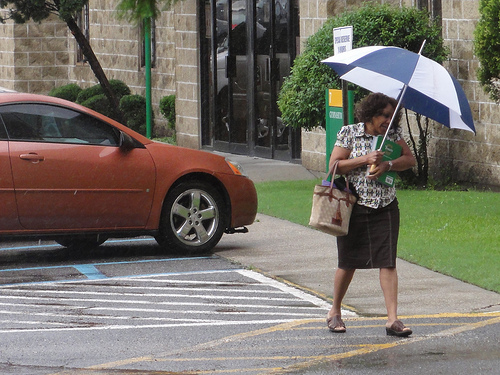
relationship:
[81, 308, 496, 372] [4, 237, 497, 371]
lines in lot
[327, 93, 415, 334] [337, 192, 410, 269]
woman has skirt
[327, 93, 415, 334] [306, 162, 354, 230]
woman carrying a tote bag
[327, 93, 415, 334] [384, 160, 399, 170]
woman wearing a watch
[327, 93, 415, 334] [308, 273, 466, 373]
woman walking on sidewalk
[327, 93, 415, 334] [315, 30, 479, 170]
woman carrying umbrella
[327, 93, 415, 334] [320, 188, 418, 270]
woman wearing a skirt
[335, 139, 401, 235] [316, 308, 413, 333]
blouse and sandals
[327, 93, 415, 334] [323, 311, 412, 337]
woman has shoes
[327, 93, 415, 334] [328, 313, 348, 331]
woman has shoe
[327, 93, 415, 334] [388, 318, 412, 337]
woman has shoe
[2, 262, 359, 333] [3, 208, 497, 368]
lines in lot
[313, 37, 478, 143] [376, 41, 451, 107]
umbrella with stripes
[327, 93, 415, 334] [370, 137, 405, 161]
woman carrying books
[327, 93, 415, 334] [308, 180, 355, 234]
woman carrying bag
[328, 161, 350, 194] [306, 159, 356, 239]
straps on bag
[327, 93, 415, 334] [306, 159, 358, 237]
woman has purse